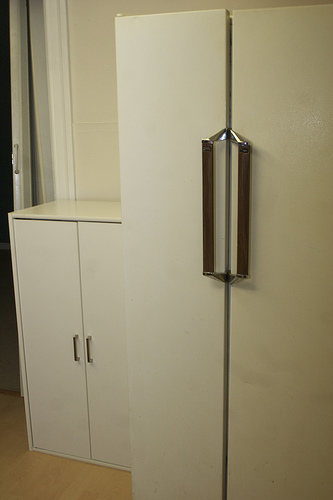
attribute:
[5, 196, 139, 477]
cabinet — shorter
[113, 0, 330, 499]
refrigerator — on the right, cream colored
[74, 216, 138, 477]
door — closed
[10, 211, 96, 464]
door — closed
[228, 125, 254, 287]
handle — woodgrain, brown, silver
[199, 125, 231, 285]
handle — woodgrain, brown, silver